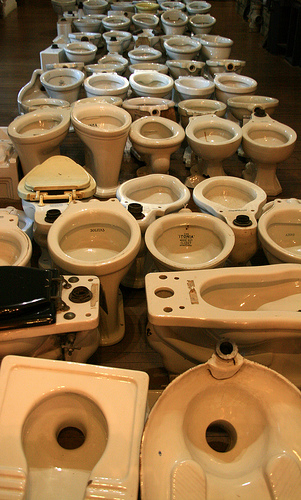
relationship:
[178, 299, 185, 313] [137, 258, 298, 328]
hole on toilet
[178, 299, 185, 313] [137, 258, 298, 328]
hole of toilet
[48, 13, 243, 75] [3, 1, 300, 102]
toilets in background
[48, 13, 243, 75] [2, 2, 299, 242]
toilets in room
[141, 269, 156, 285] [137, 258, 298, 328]
edge of toilet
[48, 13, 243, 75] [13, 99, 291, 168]
toilets in a row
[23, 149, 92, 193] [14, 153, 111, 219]
lid on toilet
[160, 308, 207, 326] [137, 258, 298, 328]
valve on a toilet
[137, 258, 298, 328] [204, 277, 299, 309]
toilet has no lid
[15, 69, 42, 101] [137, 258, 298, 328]
water basin of a toilet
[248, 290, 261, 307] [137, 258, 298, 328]
inside of a toilet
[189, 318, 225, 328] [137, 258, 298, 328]
part of a toilet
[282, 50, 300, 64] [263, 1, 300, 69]
edge of a shade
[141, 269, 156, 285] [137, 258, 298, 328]
edge of a toilet